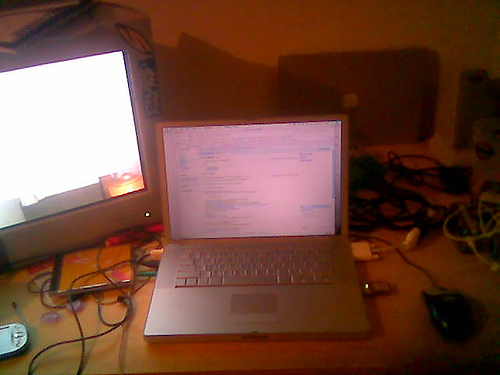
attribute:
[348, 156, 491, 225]
wires — black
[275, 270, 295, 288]
button — silver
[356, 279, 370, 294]
light — small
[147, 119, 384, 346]
laptop — on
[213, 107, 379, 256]
laptop — open laptop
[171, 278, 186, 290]
button — silver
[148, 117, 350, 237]
screen — computer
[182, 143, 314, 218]
print — black, blue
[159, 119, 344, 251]
monitor — laptop monitor, on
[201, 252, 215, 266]
button — silver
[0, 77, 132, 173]
light — bright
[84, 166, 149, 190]
picture — orange